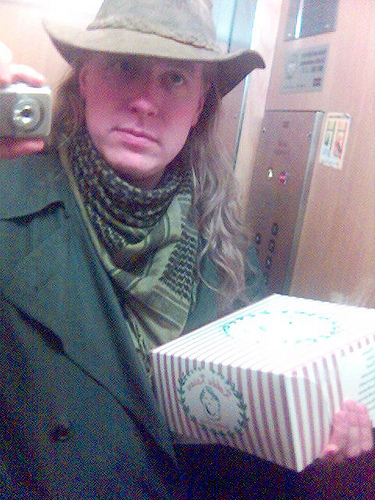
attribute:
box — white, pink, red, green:
[144, 292, 375, 475]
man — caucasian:
[2, 1, 370, 498]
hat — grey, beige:
[42, 1, 263, 94]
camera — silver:
[1, 87, 53, 138]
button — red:
[277, 173, 289, 185]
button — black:
[267, 222, 283, 238]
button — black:
[265, 239, 281, 252]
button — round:
[50, 419, 78, 444]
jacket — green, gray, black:
[1, 147, 310, 499]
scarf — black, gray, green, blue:
[55, 122, 205, 379]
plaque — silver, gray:
[274, 48, 332, 92]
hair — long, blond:
[41, 69, 253, 303]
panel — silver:
[243, 105, 327, 301]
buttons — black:
[249, 213, 284, 291]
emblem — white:
[174, 366, 254, 439]